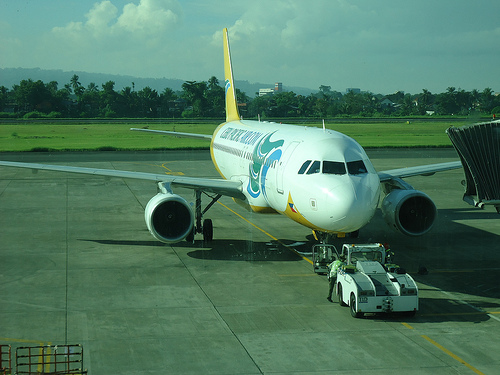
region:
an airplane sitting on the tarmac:
[4, 20, 499, 262]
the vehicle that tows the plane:
[305, 228, 432, 325]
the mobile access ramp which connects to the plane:
[442, 108, 498, 218]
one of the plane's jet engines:
[138, 178, 203, 261]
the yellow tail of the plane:
[203, 22, 250, 120]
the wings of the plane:
[1, 150, 467, 197]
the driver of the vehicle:
[324, 251, 348, 305]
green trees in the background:
[6, 85, 497, 121]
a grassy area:
[1, 121, 498, 149]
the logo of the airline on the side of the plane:
[217, 121, 288, 197]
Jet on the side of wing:
[130, 161, 207, 257]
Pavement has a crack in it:
[172, 265, 307, 370]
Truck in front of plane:
[290, 222, 440, 314]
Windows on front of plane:
[295, 145, 375, 180]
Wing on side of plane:
[5, 151, 285, 208]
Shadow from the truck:
[415, 270, 487, 335]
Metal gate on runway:
[10, 335, 115, 370]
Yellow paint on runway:
[410, 325, 476, 372]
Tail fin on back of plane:
[215, 20, 242, 135]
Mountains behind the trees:
[7, 65, 242, 81]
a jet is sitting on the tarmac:
[10, 19, 472, 299]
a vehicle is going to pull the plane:
[303, 235, 425, 320]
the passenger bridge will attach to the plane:
[320, 119, 490, 332]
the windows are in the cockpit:
[297, 157, 371, 184]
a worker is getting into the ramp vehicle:
[320, 252, 350, 309]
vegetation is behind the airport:
[15, 55, 497, 215]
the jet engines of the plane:
[142, 185, 442, 247]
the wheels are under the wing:
[183, 215, 220, 250]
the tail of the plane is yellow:
[214, 26, 244, 121]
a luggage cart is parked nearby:
[2, 333, 89, 373]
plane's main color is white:
[160, 80, 404, 239]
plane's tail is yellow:
[207, 16, 259, 131]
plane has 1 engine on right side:
[145, 183, 229, 265]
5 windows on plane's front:
[288, 136, 375, 186]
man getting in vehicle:
[312, 242, 357, 306]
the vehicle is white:
[302, 235, 422, 308]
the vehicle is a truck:
[314, 241, 429, 329]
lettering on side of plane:
[208, 121, 279, 160]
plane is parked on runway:
[2, 1, 422, 312]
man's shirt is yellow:
[321, 255, 347, 284]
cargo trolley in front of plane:
[328, 235, 426, 319]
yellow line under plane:
[167, 160, 498, 374]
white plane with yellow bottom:
[214, 170, 362, 240]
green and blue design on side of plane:
[245, 127, 284, 202]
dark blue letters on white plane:
[211, 120, 267, 154]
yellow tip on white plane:
[211, 25, 243, 121]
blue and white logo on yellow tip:
[219, 75, 234, 97]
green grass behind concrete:
[0, 116, 499, 154]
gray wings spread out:
[2, 147, 477, 189]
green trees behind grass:
[0, 76, 499, 113]